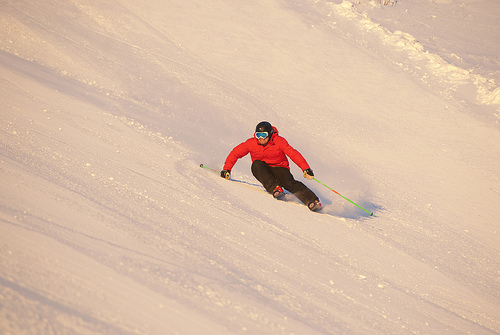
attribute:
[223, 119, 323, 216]
man — light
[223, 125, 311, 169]
jacket — red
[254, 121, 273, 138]
helmet — black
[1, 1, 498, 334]
snow — white, cut, tuft, slope, grey, pieces, leaning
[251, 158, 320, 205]
trouser — black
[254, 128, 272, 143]
goggles — blue, ski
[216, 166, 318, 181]
gloves — black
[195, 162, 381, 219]
poles — green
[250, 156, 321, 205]
pants — black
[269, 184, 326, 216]
boots — black, red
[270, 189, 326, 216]
skis — black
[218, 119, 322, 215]
person — going, skiing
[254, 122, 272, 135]
hat — black